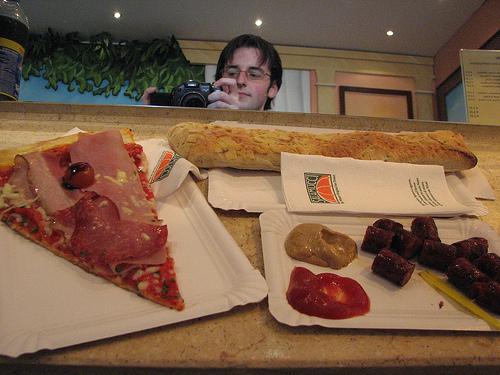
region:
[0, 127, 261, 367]
slice of pizza on a tray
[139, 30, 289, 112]
man taking a camera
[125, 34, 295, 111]
man holding a black camera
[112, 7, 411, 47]
row of three smal lights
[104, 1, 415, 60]
lights on the ceiling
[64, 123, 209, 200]
corner of the pizza on the napkin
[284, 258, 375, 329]
glob of red ketchup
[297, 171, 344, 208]
orange and green logo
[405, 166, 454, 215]
green writing on the bottom of the napkin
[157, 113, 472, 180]
large loaf of bread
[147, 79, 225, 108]
black handheld camera sitting on sidewall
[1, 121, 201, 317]
large New York style pizza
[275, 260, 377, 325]
red dipping sauce on plate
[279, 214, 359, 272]
yellow mustard dipping sauce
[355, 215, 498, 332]
brown sausage on plate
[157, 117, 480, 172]
French baguette on the plate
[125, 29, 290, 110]
man photographing displayed food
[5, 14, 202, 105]
painted green trees on wall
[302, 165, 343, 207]
Green and orange logo on napkin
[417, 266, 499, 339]
plastic yellow fork on plate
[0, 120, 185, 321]
pizza with very little cheese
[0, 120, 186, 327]
pizza with large slices of meat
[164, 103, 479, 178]
long piece of bread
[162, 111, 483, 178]
toasted breadstick with cheese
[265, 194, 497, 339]
plate with sausage and condiments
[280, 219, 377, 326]
ketchup and mustard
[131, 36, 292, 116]
man taking a picture of food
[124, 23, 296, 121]
man looking into camera viewfinder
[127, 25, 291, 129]
man wearing eyeglasses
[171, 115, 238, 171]
Small section of a loaf of bread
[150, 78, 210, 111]
Black camera being used by the man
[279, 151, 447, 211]
One of the napkins where they got the food from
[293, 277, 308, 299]
Little patch of ketchup on plate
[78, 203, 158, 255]
A piece of salami on the pizza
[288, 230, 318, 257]
Small patch of mustard on white plate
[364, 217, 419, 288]
Mini hot dog pieces on white plate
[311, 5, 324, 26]
Small part of the ceiling in the room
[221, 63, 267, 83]
Glasses of the man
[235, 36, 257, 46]
Small patch of the black hair of the man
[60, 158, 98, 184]
cherry tomato on a slice of pizza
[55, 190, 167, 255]
piece of meat on a slice of pizza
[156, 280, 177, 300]
green herbs on the tip of a pizza slice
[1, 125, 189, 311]
a slice of pizza covered in meaty toppings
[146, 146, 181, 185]
green and orange logo on a napkin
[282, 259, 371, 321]
small amount of red sauce on a plate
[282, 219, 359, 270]
brown sauce on a plate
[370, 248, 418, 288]
chopped brown piece of food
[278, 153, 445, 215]
white napkin on a table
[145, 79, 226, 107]
black camera in the man's hand